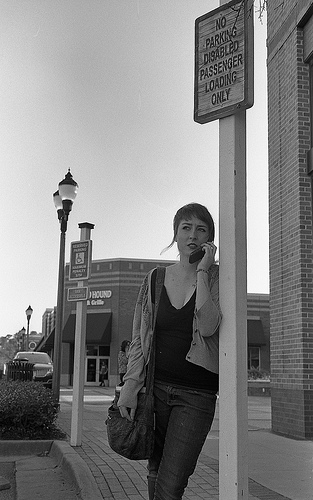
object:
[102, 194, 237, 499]
woman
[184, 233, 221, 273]
phone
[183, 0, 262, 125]
sign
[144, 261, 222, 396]
shirt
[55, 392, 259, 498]
sidewalk